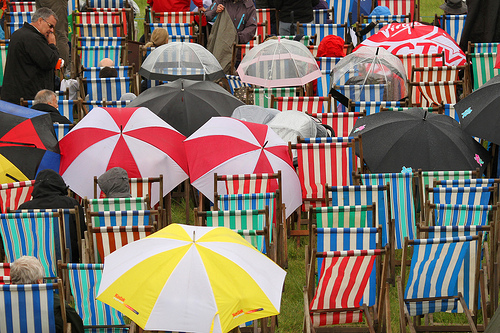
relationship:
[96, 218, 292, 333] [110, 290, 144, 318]
umbrella has writing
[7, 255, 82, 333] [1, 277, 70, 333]
person in chair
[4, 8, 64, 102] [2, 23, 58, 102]
man wearing jacket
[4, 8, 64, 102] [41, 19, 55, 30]
man wearing sunglasses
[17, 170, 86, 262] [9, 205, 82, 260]
person in chair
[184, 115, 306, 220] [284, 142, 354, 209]
umbrella next to chair